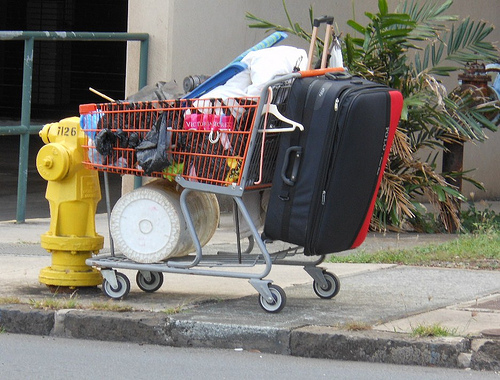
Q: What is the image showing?
A: It is showing a sidewalk.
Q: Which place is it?
A: It is a sidewalk.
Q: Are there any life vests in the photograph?
A: No, there are no life vests.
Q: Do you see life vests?
A: No, there are no life vests.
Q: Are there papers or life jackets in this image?
A: No, there are no life jackets or papers.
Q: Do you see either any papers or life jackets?
A: No, there are no life jackets or papers.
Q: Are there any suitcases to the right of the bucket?
A: Yes, there is a suitcase to the right of the bucket.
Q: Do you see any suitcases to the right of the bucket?
A: Yes, there is a suitcase to the right of the bucket.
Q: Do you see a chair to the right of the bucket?
A: No, there is a suitcase to the right of the bucket.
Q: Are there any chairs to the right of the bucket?
A: No, there is a suitcase to the right of the bucket.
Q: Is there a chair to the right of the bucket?
A: No, there is a suitcase to the right of the bucket.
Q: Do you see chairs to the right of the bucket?
A: No, there is a suitcase to the right of the bucket.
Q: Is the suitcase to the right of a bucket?
A: Yes, the suitcase is to the right of a bucket.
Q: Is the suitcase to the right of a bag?
A: No, the suitcase is to the right of a bucket.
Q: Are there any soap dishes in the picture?
A: No, there are no soap dishes.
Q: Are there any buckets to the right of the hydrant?
A: Yes, there is a bucket to the right of the hydrant.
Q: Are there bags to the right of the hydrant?
A: No, there is a bucket to the right of the hydrant.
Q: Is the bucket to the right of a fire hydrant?
A: Yes, the bucket is to the right of a fire hydrant.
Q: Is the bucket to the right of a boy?
A: No, the bucket is to the right of a fire hydrant.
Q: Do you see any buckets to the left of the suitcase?
A: Yes, there is a bucket to the left of the suitcase.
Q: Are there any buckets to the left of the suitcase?
A: Yes, there is a bucket to the left of the suitcase.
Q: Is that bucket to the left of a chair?
A: No, the bucket is to the left of a suitcase.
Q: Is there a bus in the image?
A: No, there are no buses.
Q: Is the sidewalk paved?
A: Yes, the sidewalk is paved.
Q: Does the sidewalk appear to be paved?
A: Yes, the sidewalk is paved.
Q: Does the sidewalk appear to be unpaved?
A: No, the sidewalk is paved.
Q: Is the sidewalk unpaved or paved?
A: The sidewalk is paved.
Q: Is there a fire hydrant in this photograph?
A: Yes, there is a fire hydrant.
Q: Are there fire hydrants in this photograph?
A: Yes, there is a fire hydrant.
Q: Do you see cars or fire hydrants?
A: Yes, there is a fire hydrant.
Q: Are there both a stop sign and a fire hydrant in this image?
A: No, there is a fire hydrant but no stop signs.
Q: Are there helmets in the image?
A: No, there are no helmets.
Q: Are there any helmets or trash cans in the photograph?
A: No, there are no helmets or trash cans.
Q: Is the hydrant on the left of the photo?
A: Yes, the hydrant is on the left of the image.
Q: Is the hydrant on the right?
A: No, the hydrant is on the left of the image.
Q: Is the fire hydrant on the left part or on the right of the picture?
A: The fire hydrant is on the left of the image.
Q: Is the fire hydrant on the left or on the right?
A: The fire hydrant is on the left of the image.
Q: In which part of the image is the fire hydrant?
A: The fire hydrant is on the left of the image.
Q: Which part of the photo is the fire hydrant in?
A: The fire hydrant is on the left of the image.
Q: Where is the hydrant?
A: The hydrant is on the sidewalk.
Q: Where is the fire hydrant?
A: The hydrant is on the sidewalk.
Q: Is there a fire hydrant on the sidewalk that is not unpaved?
A: Yes, there is a fire hydrant on the side walk.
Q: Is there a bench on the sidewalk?
A: No, there is a fire hydrant on the sidewalk.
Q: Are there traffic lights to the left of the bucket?
A: No, there is a fire hydrant to the left of the bucket.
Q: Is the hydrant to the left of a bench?
A: No, the hydrant is to the left of the bucket.